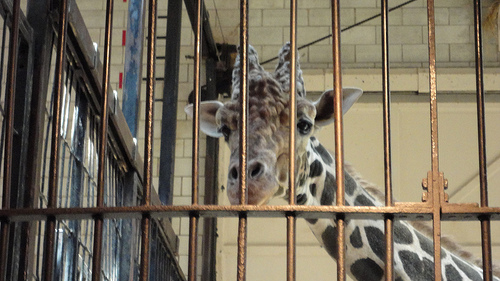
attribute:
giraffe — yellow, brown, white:
[182, 39, 493, 280]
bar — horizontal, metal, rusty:
[5, 201, 496, 216]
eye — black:
[297, 113, 315, 133]